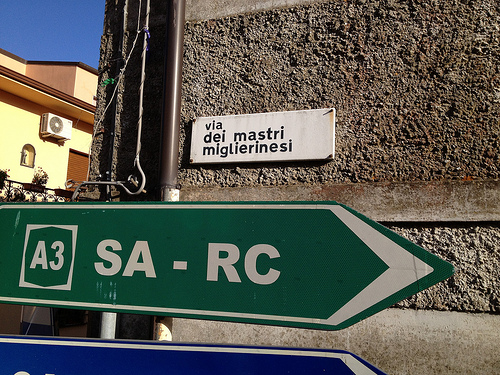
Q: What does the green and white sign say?
A: A3 SA-RC.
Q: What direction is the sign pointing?
A: Right.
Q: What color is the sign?
A: Green and white.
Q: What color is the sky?
A: Blue.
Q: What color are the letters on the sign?
A: White.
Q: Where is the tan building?
A: Left.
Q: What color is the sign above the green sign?
A: White.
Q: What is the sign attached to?
A: Metal pole.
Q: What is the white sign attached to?
A: Stone.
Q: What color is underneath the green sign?
A: Blue.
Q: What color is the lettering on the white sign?
A: Black.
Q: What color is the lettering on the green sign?
A: White.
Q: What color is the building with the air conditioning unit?
A: Yellow and brown.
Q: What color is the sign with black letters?
A: White.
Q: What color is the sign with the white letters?
A: Green.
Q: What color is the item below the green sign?
A: Blue and white.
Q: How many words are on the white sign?
A: Four.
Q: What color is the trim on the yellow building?
A: Brown.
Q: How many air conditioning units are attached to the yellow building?
A: One.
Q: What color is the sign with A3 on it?
A: Greens.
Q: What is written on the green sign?
A: A3 SA - RC.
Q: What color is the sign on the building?
A: White.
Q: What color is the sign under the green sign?
A: Blue.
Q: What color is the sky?
A: Blue.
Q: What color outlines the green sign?
A: White.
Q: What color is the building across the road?
A: Yellow.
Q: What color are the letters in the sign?
A: The letters are black.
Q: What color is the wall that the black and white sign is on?
A: The wall is brownish.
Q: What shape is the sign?
A: The sign is rectangular.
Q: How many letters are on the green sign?
A: Five.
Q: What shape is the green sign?
A: An arrow.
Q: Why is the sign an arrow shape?
A: To point a traveler in the right direction.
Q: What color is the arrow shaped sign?
A: Green.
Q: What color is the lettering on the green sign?
A: White.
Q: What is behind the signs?
A: A concrete wall.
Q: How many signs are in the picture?
A: Three.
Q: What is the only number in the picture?
A: Three.